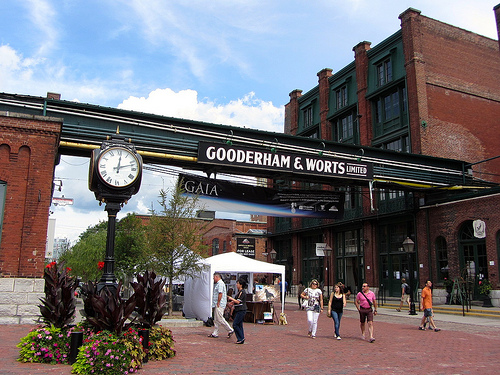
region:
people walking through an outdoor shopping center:
[297, 276, 379, 341]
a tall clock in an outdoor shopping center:
[85, 125, 140, 303]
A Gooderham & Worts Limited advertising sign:
[193, 140, 373, 185]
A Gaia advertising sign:
[173, 173, 271, 203]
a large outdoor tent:
[200, 251, 290, 313]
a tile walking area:
[0, 298, 497, 373]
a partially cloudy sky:
[0, 2, 497, 129]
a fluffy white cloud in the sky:
[113, 87, 283, 130]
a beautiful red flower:
[96, 258, 105, 272]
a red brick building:
[1, 115, 64, 280]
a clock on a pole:
[86, 126, 151, 316]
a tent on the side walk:
[173, 251, 290, 328]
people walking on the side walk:
[296, 271, 385, 343]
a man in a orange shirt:
[413, 276, 442, 333]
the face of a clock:
[101, 139, 138, 194]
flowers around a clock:
[32, 138, 180, 363]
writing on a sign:
[194, 144, 381, 177]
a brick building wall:
[410, 31, 483, 156]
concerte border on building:
[4, 279, 63, 326]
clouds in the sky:
[120, 15, 271, 104]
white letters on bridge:
[190, 141, 367, 176]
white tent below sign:
[170, 218, 314, 339]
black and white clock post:
[77, 120, 157, 222]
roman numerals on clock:
[100, 148, 150, 196]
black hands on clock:
[106, 148, 133, 200]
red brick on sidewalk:
[200, 308, 462, 370]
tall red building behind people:
[301, 32, 497, 266]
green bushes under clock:
[34, 309, 152, 374]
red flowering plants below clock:
[27, 260, 163, 342]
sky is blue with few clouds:
[82, 10, 268, 107]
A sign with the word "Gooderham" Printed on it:
[202, 138, 294, 183]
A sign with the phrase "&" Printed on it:
[290, 154, 305, 171]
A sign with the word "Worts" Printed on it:
[307, 155, 347, 182]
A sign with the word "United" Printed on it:
[345, 161, 373, 178]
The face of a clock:
[98, 149, 142, 186]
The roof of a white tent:
[192, 247, 287, 271]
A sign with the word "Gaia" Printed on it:
[170, 179, 235, 200]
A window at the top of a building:
[368, 52, 398, 91]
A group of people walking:
[300, 268, 450, 353]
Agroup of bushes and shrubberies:
[20, 262, 177, 374]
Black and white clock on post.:
[86, 123, 142, 310]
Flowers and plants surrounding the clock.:
[15, 256, 181, 372]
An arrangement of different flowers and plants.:
[16, 260, 176, 373]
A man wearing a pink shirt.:
[356, 280, 377, 342]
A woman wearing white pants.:
[300, 275, 323, 336]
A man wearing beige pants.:
[207, 268, 230, 340]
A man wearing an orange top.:
[416, 277, 441, 330]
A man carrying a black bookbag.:
[395, 275, 410, 312]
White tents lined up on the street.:
[125, 240, 291, 324]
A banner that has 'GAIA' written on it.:
[177, 171, 346, 219]